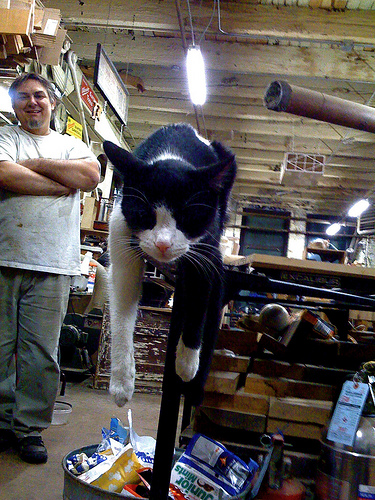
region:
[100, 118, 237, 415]
black and white cat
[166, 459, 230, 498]
box of Junior Mints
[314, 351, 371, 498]
silver fire extinguisher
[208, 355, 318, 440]
stack of cut lumber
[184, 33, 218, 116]
overhead flourescent lighting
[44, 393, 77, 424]
empty water bowl for cat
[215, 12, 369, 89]
unfinished wooden ceiling beams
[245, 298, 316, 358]
rusted ball and hitch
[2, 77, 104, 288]
man in dirty white tshirt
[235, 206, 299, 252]
baorded up window in back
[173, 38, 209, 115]
a florescent on the ceiling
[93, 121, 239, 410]
a black and white cat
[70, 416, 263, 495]
trash in a garbage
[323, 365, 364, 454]
tag on a fire hydrant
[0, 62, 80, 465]
a man with his arms crossed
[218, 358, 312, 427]
a small pile of wood boards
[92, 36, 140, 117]
a sign hanging from the ceiling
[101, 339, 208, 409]
the black and white cats paws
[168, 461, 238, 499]
an empty box of junior mints in the garbage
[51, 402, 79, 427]
a plastic bowl on the ground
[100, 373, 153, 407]
tip of cat's white foot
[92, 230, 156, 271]
white whiskers on cat's face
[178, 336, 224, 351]
black edge of cat's foot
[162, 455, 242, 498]
packet of little candy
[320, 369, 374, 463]
white and blue tag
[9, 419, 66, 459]
black shoe on man's foot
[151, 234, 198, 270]
pink nose on cat's face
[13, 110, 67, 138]
salt and pepper moustache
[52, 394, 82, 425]
white bowl on floor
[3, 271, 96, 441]
man wearing dirty blue jeans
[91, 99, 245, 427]
Cat lying on edge on a table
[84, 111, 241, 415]
Cat is sleeping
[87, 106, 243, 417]
Cat is black and white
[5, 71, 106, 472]
Man is with crossing arms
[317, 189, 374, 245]
Lights inside the store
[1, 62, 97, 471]
man wears a dirty t-shirt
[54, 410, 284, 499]
Bags in a container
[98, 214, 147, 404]
leg of cat is white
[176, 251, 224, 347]
Leg of cat is black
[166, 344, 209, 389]
Paw of cat is white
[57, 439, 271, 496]
garbage can full of paper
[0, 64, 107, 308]
man standing with arms crossed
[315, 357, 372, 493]
fire extinguisher with tag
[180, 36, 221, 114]
light suspended from ceiling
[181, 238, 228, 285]
cat's white whiskers on face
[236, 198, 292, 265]
window on back wall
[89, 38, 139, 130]
sign hanging from two wires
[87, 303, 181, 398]
wood furniture with worn paint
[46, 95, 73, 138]
clocks on side wall